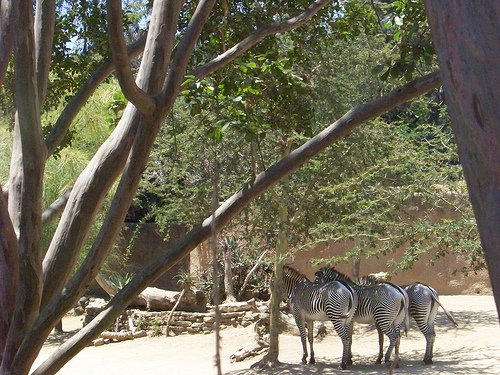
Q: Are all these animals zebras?
A: Yes, all the animals are zebras.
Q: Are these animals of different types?
A: No, all the animals are zebras.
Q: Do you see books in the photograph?
A: No, there are no books.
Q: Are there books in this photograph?
A: No, there are no books.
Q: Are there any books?
A: No, there are no books.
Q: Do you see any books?
A: No, there are no books.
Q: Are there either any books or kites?
A: No, there are no books or kites.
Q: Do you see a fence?
A: No, there are no fences.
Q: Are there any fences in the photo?
A: No, there are no fences.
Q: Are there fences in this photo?
A: No, there are no fences.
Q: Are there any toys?
A: No, there are no toys.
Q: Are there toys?
A: No, there are no toys.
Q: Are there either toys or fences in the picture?
A: No, there are no toys or fences.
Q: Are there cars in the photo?
A: No, there are no cars.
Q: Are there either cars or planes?
A: No, there are no cars or planes.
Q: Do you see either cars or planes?
A: No, there are no cars or planes.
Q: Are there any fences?
A: No, there are no fences.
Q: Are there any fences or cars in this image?
A: No, there are no fences or cars.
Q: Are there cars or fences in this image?
A: No, there are no fences or cars.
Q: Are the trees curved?
A: Yes, the trees are curved.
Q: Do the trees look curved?
A: Yes, the trees are curved.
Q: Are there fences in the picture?
A: No, there are no fences.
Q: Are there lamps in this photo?
A: No, there are no lamps.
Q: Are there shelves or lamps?
A: No, there are no lamps or shelves.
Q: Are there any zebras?
A: Yes, there are zebras.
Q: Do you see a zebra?
A: Yes, there are zebras.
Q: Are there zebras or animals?
A: Yes, there are zebras.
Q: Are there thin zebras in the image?
A: Yes, there are thin zebras.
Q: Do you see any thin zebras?
A: Yes, there are thin zebras.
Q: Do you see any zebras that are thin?
A: Yes, there are zebras that are thin.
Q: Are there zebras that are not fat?
A: Yes, there are thin zebras.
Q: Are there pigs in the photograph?
A: No, there are no pigs.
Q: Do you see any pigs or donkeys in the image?
A: No, there are no pigs or donkeys.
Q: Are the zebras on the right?
A: Yes, the zebras are on the right of the image.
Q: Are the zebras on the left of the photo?
A: No, the zebras are on the right of the image.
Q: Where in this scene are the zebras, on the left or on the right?
A: The zebras are on the right of the image.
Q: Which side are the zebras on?
A: The zebras are on the right of the image.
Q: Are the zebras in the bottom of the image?
A: Yes, the zebras are in the bottom of the image.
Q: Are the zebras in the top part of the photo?
A: No, the zebras are in the bottom of the image.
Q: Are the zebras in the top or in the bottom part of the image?
A: The zebras are in the bottom of the image.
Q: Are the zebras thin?
A: Yes, the zebras are thin.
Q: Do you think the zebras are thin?
A: Yes, the zebras are thin.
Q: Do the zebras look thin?
A: Yes, the zebras are thin.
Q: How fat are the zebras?
A: The zebras are thin.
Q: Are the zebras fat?
A: No, the zebras are thin.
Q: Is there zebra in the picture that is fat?
A: No, there are zebras but they are thin.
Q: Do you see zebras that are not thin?
A: No, there are zebras but they are thin.